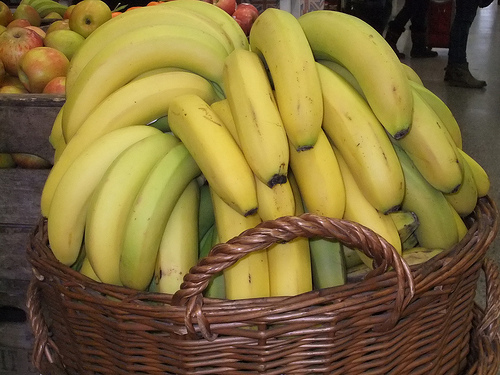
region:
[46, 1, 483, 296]
Bananas bunched together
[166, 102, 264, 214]
Yellow banana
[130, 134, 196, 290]
Green banana that is not ripe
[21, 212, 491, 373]
Brown wicker basket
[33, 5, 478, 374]
Bananas in a brown basket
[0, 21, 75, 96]
Apples that are bunched together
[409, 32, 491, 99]
Someones feet in the background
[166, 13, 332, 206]
Three bananas in the front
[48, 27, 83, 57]
Green apple on table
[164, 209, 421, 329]
Handle on a brown basket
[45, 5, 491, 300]
There is a large bunch of bananas.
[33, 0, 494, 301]
The bananas are ripe.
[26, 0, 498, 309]
The bananas are very healthy.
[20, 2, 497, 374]
The bananas are in a basket.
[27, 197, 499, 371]
The basket is woven.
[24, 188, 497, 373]
The basket is brown.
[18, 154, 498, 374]
The basket has handles.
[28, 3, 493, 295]
The bananas are unpeeled.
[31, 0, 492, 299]
The bananas are portable.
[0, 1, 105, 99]
The apples are round.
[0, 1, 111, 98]
greenish apples that are unripe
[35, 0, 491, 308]
large bunch of yellow bananas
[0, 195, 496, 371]
brown woven wicker basket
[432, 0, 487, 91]
person's leg in the background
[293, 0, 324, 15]
faded british flag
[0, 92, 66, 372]
worn wooden fruit crate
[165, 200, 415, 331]
handle of brown woven wicker basket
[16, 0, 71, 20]
bananas in the background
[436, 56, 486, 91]
person's shoe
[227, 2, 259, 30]
shiny red ripe apple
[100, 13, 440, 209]
yellow bananas in basket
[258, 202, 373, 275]
handle of a basket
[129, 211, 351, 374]
brown basket holding fruit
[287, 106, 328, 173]
bottom part of banana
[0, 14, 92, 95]
round fruit next to bananas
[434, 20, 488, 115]
leg and foot of a person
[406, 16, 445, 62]
distant leg of a person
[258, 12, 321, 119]
banana on top of stack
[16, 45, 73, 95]
red and green fruit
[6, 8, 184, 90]
two different kinds of fruit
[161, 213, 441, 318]
a handle for a brown weave basket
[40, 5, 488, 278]
a bunch of bananas in a weave basket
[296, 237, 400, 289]
in a weave basket is a green banana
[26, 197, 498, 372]
a brown weave basket holding bananas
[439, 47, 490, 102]
a brown pair of boots on the floor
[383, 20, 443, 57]
on the floor is a person wearing black shoes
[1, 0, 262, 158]
a bunch of apples in a purple container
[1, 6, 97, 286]
a purple container holding apples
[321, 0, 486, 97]
many people are wearing shoes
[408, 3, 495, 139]
a portion of a red door in background